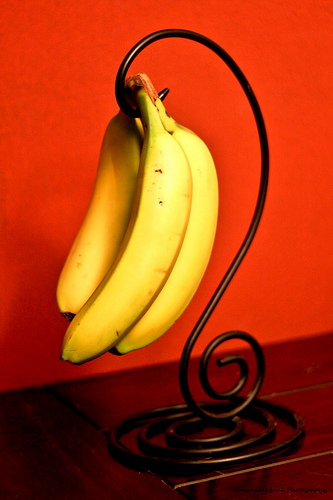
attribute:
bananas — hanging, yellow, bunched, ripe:
[57, 73, 219, 365]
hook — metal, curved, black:
[107, 28, 171, 118]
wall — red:
[1, 0, 331, 395]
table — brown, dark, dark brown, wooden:
[1, 332, 332, 500]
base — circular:
[109, 396, 306, 471]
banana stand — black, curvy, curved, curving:
[107, 29, 305, 469]